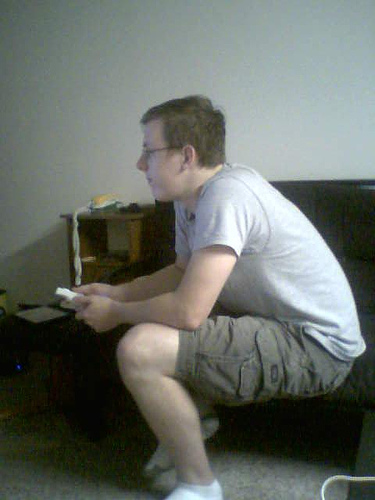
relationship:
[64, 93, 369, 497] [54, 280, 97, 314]
man holding game controller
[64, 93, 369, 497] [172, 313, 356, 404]
man wearing cargo shorts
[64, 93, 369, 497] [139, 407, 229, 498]
man wearing socks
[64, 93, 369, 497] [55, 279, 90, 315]
man holding game controller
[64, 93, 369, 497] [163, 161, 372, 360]
man has a shirt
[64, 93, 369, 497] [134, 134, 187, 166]
man wearing eye glasses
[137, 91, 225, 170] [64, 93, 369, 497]
hair of man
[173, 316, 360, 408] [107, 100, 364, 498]
shorts on man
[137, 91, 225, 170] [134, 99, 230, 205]
hair on h head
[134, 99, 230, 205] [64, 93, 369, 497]
head of man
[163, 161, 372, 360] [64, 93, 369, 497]
shirt on man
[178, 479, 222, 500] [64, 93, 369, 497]
socks on feet of man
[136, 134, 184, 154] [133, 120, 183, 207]
eye glasses on h face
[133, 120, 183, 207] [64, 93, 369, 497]
face of man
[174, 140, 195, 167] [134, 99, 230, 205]
ear on h head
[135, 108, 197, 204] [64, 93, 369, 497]
face of man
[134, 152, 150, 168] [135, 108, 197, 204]
nose on h face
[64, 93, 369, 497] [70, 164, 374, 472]
man sitting on couch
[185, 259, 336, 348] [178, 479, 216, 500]
man wearing socks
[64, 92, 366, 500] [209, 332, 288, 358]
man wearing shorts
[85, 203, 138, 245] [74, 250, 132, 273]
stand has shelfs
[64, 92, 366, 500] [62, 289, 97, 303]
man has remote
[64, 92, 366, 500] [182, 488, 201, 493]
man has socks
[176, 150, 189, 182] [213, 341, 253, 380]
man has shorts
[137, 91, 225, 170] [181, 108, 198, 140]
hair has hair